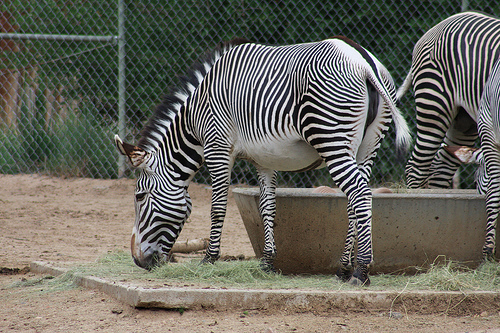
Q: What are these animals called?
A: Zebras.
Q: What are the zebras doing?
A: Eating.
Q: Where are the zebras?
A: In captivity.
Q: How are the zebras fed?
A: Grass and Hay.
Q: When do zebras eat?
A: When they are hungry.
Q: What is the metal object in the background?
A: Fence.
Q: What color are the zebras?
A: Black and white.